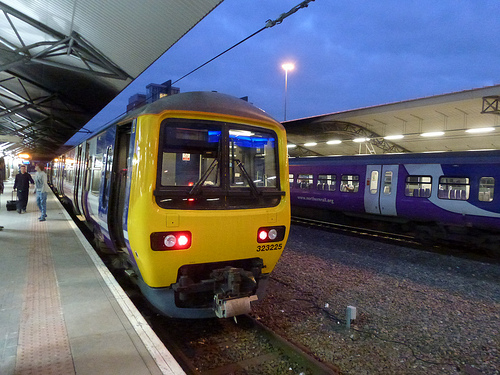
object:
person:
[30, 161, 51, 223]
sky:
[61, 2, 498, 155]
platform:
[0, 172, 203, 375]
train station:
[1, 0, 500, 375]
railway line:
[64, 199, 350, 375]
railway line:
[290, 213, 498, 264]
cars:
[378, 148, 500, 260]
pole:
[282, 69, 288, 121]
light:
[277, 58, 296, 74]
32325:
[256, 243, 283, 253]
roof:
[0, 0, 225, 174]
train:
[288, 146, 500, 258]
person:
[12, 163, 36, 214]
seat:
[412, 188, 419, 198]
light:
[280, 59, 296, 124]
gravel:
[265, 214, 500, 375]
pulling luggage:
[6, 163, 35, 214]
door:
[105, 115, 137, 270]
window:
[155, 115, 282, 212]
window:
[403, 174, 433, 199]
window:
[437, 175, 472, 201]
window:
[339, 174, 360, 194]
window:
[316, 173, 337, 193]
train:
[34, 79, 300, 324]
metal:
[170, 265, 270, 325]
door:
[363, 160, 401, 218]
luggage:
[5, 188, 19, 213]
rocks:
[315, 265, 462, 351]